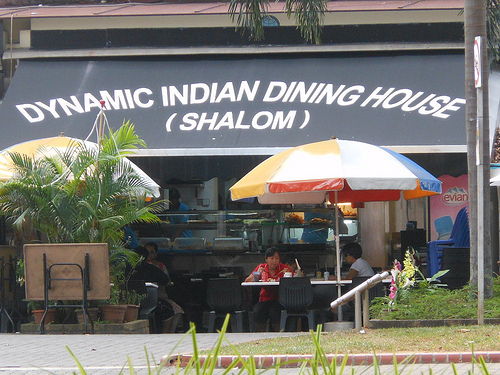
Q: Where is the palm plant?
A: In front of yellow, white umbrella.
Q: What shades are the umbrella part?
A: Yellow, white, blue, red.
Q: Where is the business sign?
A: On business.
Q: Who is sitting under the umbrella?
A: Customers.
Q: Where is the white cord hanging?
A: In palm plant.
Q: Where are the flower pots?
A: Behind the folded table.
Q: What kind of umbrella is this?
A: Multicolored.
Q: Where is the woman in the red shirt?
A: Sitting at a table under an umbrella.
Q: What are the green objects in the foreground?
A: Blades of grass.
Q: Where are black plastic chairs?
A: At the tables.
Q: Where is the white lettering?
A: On black awning.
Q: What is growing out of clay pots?
A: Plants.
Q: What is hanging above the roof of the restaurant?
A: Palm fronds.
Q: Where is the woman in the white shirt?
A: Under the umbrella.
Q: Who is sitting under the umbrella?
A: Two women.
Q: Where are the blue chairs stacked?
A: On the far right behind a palm tree.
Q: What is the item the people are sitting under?
A: Umbrella.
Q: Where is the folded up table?
A: In front of palm tree.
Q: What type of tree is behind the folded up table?
A: Palm.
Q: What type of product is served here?
A: Food.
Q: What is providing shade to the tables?
A: Umbrellas.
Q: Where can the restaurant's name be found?
A: Awning.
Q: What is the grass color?
A: Green.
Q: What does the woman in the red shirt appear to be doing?
A: Eating.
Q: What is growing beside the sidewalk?
A: Grass.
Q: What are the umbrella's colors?
A: Orange, yellow, white and blue.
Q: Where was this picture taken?
A: Outside a restaurant.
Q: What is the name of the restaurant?
A: Dynamic Indian Dining House.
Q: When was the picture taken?
A: Daytime.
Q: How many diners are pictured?
A: Four.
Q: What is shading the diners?
A: Umbrellas.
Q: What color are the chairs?
A: Black.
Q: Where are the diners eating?
A: Outside veranda.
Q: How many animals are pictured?
A: None.